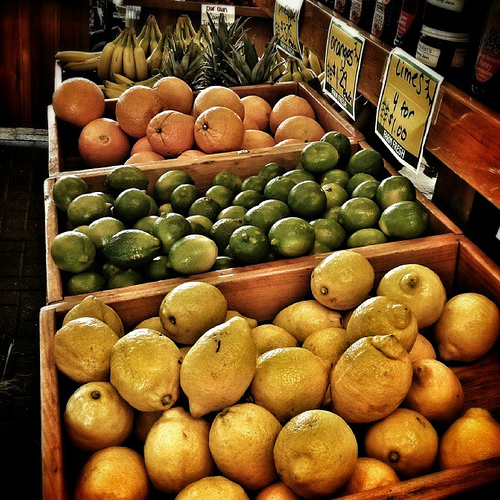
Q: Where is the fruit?
A: In box.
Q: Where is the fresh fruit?
A: In box.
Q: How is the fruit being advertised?
A: Signs.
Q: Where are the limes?
A: A bin.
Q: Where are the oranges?
A: In bin.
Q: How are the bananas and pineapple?
A: For sale.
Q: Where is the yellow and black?
A: On sign.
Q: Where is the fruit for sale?
A: In store.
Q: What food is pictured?
A: Fruit.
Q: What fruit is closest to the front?
A: Lemons.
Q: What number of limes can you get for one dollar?
A: Four.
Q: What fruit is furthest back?
A: Bananas.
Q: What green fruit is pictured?
A: Limes.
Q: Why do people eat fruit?
A: Health.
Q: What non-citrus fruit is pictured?
A: Bananas.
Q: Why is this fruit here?
A: To be sold.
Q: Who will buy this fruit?
A: Customers.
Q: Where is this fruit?
A: In a store.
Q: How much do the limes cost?
A: Four for $1.00.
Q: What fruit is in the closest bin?
A: Lemons.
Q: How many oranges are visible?
A: Fifteen.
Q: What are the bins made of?
A: Wood.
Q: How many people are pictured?
A: None.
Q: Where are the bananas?
A: In the bin farthest from the camera.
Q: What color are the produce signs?
A: Yellow and black.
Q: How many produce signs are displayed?
A: Three.